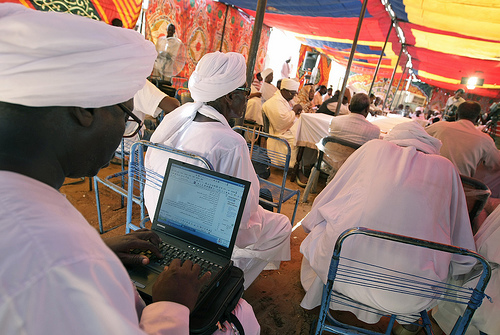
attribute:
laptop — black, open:
[110, 152, 252, 309]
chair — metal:
[129, 135, 227, 238]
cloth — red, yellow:
[275, 18, 424, 96]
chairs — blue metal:
[144, 107, 499, 333]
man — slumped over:
[291, 102, 472, 320]